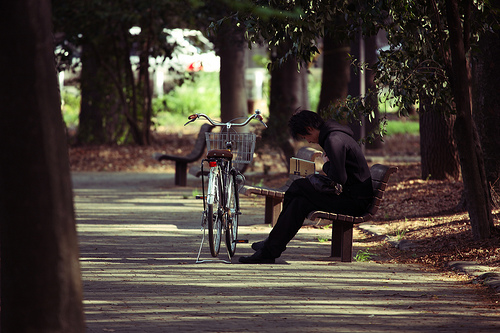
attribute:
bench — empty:
[158, 115, 215, 192]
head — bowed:
[287, 108, 319, 140]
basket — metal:
[206, 132, 261, 169]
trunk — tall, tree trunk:
[324, 60, 394, 250]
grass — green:
[362, 87, 437, 127]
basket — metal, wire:
[203, 129, 258, 164]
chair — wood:
[310, 163, 397, 262]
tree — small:
[367, 2, 497, 267]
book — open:
[287, 152, 319, 178]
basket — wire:
[204, 131, 258, 161]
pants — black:
[257, 177, 369, 259]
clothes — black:
[246, 135, 380, 261]